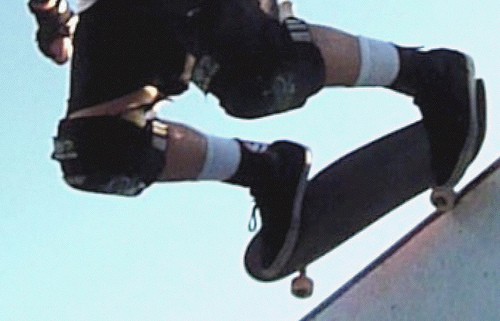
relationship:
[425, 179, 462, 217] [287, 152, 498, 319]
wheel touching ramp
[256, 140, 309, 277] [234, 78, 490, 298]
foot on skateboard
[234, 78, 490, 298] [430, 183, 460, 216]
skateboard has wheel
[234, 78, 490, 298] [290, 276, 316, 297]
skateboard has wheel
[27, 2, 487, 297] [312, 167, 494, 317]
skate boarder on top of half pipe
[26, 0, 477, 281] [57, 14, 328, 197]
skater wearing knee pads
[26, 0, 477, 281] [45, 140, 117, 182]
skater wearing knee pad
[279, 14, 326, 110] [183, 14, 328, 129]
velcro on knee pads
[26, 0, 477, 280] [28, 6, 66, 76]
skater wearing glove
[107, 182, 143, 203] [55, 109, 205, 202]
brand name on kneepad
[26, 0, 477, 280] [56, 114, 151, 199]
skater with knee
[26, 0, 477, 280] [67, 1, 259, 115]
skater wearing shorts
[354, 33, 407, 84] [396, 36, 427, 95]
sock under ankle band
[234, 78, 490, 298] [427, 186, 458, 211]
skateboard has wheels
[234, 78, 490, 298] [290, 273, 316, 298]
skateboard has wheels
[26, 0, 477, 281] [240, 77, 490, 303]
skater perched on skateboard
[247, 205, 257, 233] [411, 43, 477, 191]
shoelace on shoe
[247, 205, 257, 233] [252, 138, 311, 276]
shoelace on shoe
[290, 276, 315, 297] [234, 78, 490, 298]
wheel on skateboard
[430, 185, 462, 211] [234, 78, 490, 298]
wheel on skateboard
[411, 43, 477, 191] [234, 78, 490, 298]
shoe on skateboard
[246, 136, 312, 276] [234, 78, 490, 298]
shoe on skateboard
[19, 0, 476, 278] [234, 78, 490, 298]
man on skateboard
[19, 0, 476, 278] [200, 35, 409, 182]
man wearing socks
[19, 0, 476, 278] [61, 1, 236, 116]
man wearing black shorts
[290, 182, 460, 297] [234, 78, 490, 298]
wheels on skateboard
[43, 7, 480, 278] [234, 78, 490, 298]
man on skateboard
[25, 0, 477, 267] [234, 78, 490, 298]
man on skateboard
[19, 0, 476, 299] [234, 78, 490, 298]
man on skateboard